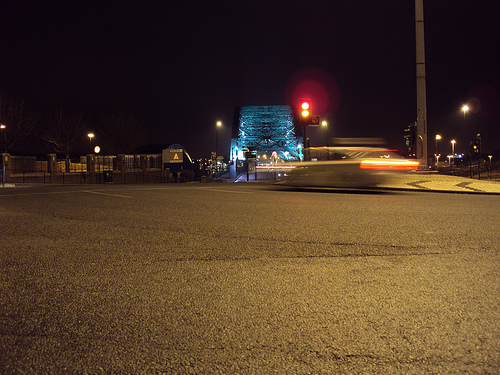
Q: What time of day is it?
A: Nighttime.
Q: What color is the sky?
A: Black.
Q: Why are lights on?
A: It's night.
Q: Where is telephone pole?
A: Top left.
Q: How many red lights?
A: 2.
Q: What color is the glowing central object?
A: Blue.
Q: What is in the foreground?
A: Pavement.